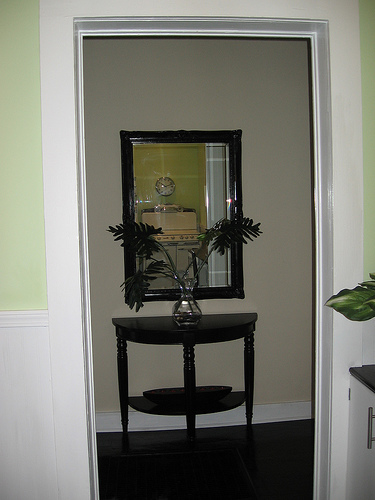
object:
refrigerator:
[142, 204, 200, 289]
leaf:
[323, 286, 374, 322]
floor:
[98, 419, 316, 498]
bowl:
[142, 383, 230, 402]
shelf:
[128, 393, 246, 414]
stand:
[112, 311, 255, 451]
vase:
[170, 271, 203, 327]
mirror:
[132, 142, 232, 294]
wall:
[82, 36, 312, 435]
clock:
[155, 177, 175, 196]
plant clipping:
[108, 222, 192, 313]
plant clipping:
[122, 261, 201, 315]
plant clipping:
[181, 217, 262, 272]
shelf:
[112, 312, 256, 344]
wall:
[1, 0, 48, 312]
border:
[1, 310, 57, 499]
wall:
[359, 1, 374, 278]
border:
[351, 367, 374, 391]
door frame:
[40, 1, 363, 499]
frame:
[119, 130, 241, 302]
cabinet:
[346, 365, 374, 499]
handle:
[367, 408, 374, 450]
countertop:
[348, 364, 373, 392]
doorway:
[82, 34, 310, 500]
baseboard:
[97, 402, 313, 433]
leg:
[115, 335, 129, 436]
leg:
[181, 345, 197, 450]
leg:
[243, 334, 255, 430]